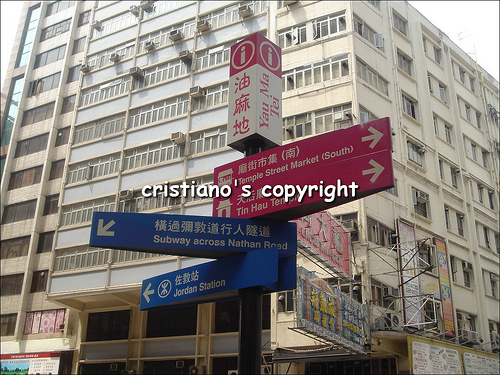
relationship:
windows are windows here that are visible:
[368, 43, 489, 282] [202, 170, 484, 341]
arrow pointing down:
[360, 125, 387, 151] [88, 196, 181, 301]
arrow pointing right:
[361, 126, 384, 148] [126, 290, 175, 353]